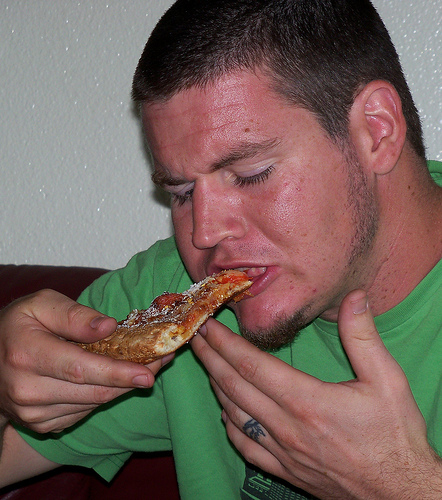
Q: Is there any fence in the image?
A: No, there are no fences.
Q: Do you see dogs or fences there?
A: No, there are no fences or dogs.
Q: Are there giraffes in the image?
A: No, there are no giraffes.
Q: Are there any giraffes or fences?
A: No, there are no giraffes or fences.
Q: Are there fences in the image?
A: No, there are no fences.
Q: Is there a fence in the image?
A: No, there are no fences.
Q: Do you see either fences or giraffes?
A: No, there are no fences or giraffes.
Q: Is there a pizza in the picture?
A: Yes, there is a pizza.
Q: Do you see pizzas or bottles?
A: Yes, there is a pizza.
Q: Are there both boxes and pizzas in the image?
A: No, there is a pizza but no boxes.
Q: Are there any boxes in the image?
A: No, there are no boxes.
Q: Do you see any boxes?
A: No, there are no boxes.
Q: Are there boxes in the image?
A: No, there are no boxes.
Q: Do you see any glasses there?
A: No, there are no glasses.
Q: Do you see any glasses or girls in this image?
A: No, there are no glasses or girls.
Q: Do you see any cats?
A: No, there are no cats.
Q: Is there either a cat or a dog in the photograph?
A: No, there are no cats or dogs.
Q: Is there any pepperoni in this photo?
A: Yes, there is pepperoni.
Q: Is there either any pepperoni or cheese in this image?
A: Yes, there is pepperoni.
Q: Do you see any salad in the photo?
A: No, there is no salad.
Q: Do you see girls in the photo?
A: No, there are no girls.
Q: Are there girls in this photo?
A: No, there are no girls.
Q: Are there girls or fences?
A: No, there are no girls or fences.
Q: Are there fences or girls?
A: No, there are no girls or fences.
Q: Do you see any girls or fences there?
A: No, there are no girls or fences.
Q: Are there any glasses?
A: No, there are no glasses.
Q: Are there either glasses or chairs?
A: No, there are no glasses or chairs.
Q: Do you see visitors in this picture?
A: No, there are no visitors.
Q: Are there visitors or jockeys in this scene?
A: No, there are no visitors or jockeys.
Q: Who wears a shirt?
A: The man wears a shirt.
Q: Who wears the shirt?
A: The man wears a shirt.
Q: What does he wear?
A: The man wears a shirt.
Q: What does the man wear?
A: The man wears a shirt.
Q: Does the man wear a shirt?
A: Yes, the man wears a shirt.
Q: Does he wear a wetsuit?
A: No, the man wears a shirt.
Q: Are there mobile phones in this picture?
A: No, there are no mobile phones.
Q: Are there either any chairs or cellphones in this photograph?
A: No, there are no cellphones or chairs.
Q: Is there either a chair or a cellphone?
A: No, there are no cell phones or chairs.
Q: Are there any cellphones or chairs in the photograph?
A: No, there are no cellphones or chairs.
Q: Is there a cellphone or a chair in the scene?
A: No, there are no cell phones or chairs.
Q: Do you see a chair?
A: No, there are no chairs.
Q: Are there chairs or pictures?
A: No, there are no chairs or pictures.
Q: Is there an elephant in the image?
A: No, there are no elephants.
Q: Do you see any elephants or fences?
A: No, there are no elephants or fences.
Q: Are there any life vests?
A: No, there are no life vests.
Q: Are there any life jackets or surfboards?
A: No, there are no life jackets or surfboards.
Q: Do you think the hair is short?
A: Yes, the hair is short.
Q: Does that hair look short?
A: Yes, the hair is short.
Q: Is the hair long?
A: No, the hair is short.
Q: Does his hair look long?
A: No, the hair is short.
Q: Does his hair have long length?
A: No, the hair is short.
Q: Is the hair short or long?
A: The hair is short.